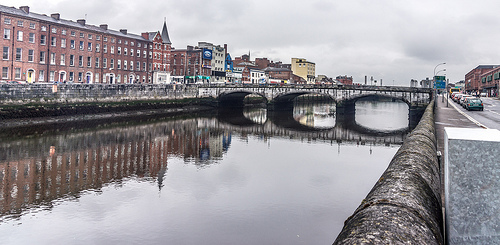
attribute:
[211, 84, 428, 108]
bridge — long, stone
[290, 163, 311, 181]
water — long, large, in city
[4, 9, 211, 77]
building — long, tall, distant, red, large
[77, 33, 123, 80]
windows — abundant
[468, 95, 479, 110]
cars — parked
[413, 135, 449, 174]
pipe — gray, long, white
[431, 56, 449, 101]
street lights — 3, rowed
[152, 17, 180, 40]
roof — pointy, on left, tower, steeple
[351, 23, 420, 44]
cloud — gray, large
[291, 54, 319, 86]
building — tan, distant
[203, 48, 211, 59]
sign — blue